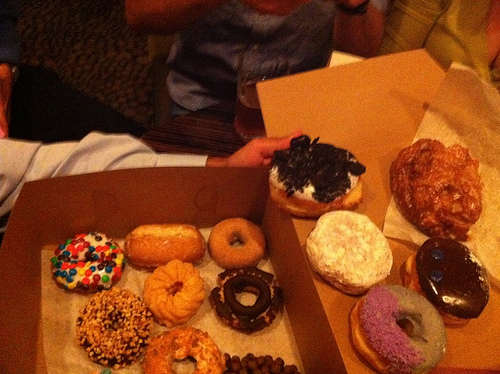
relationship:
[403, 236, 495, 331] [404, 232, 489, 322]
donut has cream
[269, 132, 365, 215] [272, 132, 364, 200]
donut has topping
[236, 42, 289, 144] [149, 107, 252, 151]
glass on table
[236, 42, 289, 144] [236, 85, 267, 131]
glass half full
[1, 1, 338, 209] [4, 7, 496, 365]
people in photo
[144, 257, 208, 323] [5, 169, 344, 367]
doughnut in box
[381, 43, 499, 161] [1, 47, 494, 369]
corner of box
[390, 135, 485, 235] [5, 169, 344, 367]
doughnut in corner of box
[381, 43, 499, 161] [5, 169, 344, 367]
corner of box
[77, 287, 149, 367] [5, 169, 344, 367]
doughnut in box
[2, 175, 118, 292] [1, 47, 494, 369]
corner of box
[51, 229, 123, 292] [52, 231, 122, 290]
donut with candies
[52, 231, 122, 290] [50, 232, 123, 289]
candies on top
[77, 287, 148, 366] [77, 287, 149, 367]
peanuts covered doughnut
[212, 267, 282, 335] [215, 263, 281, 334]
chocolate covered doughnut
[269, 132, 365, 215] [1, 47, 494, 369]
doughnut on box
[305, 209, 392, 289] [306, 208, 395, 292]
powder covered donut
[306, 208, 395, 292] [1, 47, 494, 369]
donut on box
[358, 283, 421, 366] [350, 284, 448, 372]
sprinkles on donut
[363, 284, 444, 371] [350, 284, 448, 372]
purple on donut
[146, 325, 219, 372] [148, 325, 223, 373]
cookie on donut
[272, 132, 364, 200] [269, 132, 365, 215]
crumbs on donut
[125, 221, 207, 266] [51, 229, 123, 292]
doughnut between doughnut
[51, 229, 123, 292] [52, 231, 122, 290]
doughnut with candies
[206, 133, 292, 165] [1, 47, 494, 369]
hand holding box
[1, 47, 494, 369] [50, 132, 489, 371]
box various donuts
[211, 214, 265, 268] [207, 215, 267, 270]
plain left donut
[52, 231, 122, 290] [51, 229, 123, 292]
m&m left donut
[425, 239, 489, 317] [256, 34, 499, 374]
chocolate frosted lid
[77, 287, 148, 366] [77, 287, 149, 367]
nuts cover doughnut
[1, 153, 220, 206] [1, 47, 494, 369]
arm holds box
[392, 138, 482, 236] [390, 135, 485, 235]
sticky large bun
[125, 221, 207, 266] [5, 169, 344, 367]
doughnut in box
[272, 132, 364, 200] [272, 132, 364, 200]
cookie on topping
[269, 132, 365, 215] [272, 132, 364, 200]
doughnut with frosted topping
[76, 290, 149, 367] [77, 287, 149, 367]
chocolate covered doughnut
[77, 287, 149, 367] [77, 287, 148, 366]
doughnut with nuts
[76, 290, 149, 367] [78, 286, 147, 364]
chocolate on top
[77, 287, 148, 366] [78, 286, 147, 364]
nuts on top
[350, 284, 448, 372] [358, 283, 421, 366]
doughnut dipped in sprinkles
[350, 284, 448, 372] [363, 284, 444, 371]
doughnut dipped in purple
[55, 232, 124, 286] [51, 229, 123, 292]
cream curler doughnut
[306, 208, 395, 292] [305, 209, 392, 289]
doughnut covered in sugar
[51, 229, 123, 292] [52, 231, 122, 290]
doughnut with candy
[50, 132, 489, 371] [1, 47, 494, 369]
doughnuts in box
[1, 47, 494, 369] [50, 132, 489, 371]
box filled with doughnuts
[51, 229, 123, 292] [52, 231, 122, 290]
donuts with candy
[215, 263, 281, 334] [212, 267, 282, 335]
doughnut with chocolate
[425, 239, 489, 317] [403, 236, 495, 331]
chocolate frosted doughnut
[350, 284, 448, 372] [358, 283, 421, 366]
doughnut with sprinkles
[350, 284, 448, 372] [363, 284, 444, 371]
doughnut with purple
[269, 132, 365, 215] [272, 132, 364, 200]
doughnut with toppings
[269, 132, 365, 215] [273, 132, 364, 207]
doughnut with cookie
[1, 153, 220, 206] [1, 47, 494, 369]
arm holding box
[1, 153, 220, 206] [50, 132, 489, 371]
arm holding doughnuts